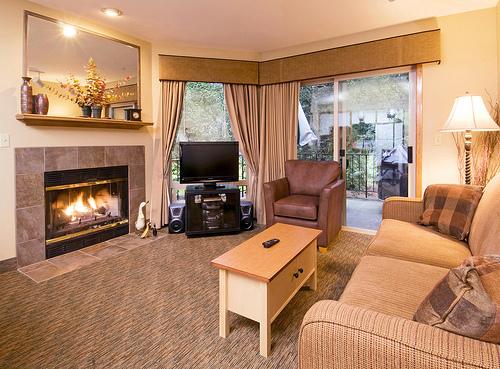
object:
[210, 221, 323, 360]
table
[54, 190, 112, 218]
fire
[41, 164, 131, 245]
fireplace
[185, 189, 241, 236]
stand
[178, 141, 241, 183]
tv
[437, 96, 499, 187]
lamp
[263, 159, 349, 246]
chair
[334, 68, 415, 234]
doors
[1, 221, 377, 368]
floor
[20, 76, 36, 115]
vases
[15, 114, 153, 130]
shelf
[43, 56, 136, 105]
flower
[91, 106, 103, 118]
pot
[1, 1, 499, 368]
room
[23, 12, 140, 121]
mirror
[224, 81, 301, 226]
draperies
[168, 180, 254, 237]
entertainment center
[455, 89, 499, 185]
grasses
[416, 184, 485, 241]
pillows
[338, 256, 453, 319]
carpeting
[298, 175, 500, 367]
sofa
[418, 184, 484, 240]
pillow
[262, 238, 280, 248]
control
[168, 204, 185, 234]
speaker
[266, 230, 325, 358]
storage area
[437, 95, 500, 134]
shade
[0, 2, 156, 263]
wall